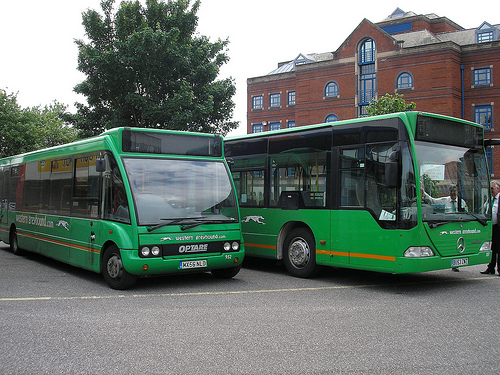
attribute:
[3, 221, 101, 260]
line — orange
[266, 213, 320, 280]
wheel — large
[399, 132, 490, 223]
window — wide, large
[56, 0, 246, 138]
tree — green, tall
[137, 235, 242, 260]
lights — white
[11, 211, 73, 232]
symbol — white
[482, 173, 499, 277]
man — standing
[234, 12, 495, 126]
buildings — tall, brick, large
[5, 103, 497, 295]
buses — large, green, here, off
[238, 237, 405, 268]
stripe — orange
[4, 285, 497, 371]
pavement — gray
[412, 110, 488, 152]
route — displayed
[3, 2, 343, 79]
sky — gray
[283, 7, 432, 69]
top of building — pointed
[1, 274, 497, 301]
line — large, white